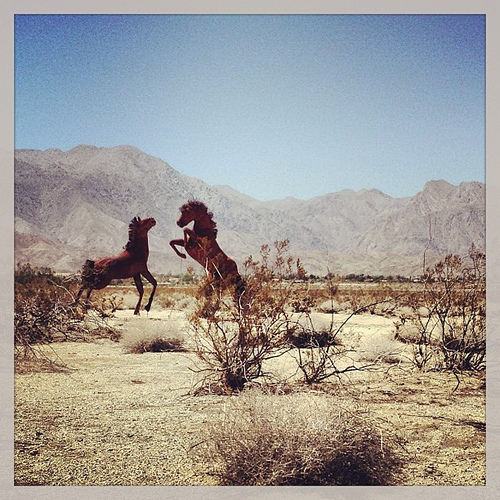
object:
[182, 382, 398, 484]
bush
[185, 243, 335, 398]
bush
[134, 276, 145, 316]
leg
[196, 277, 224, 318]
hind legs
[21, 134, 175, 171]
peak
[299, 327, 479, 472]
weeds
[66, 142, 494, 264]
mountain range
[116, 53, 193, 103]
clouds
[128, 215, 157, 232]
head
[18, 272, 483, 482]
ground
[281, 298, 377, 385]
twigs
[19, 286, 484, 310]
grass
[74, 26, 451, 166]
blue sky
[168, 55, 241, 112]
clouds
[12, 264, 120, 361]
bush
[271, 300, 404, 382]
sticks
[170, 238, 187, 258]
leg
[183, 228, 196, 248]
leg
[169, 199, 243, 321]
horse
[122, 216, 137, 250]
hair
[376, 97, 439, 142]
clouds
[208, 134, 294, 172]
clouds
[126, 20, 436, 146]
sky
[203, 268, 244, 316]
legs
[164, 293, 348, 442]
land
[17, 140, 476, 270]
mountain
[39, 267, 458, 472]
dirt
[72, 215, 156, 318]
horse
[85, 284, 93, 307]
leg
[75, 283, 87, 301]
leg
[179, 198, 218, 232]
hair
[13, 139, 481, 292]
background